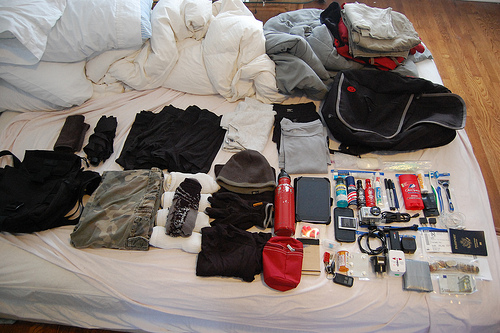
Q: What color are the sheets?
A: White.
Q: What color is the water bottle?
A: Red.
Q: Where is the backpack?
A: Top of picture.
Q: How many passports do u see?
A: 1.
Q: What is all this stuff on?
A: A bed.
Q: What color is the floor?
A: Brown.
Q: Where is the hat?
A: Middle of picture.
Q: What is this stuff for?
A: A trip.